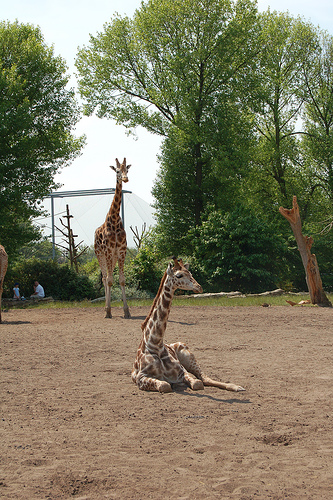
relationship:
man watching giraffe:
[29, 278, 45, 300] [82, 150, 148, 326]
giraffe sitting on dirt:
[132, 255, 238, 394] [10, 329, 328, 488]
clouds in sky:
[52, 39, 145, 142] [6, 7, 318, 228]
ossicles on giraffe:
[113, 155, 127, 165] [81, 153, 135, 319]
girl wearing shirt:
[11, 284, 22, 297] [11, 289, 26, 298]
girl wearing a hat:
[11, 284, 22, 300] [13, 282, 18, 285]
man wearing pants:
[21, 275, 49, 309] [26, 288, 44, 305]